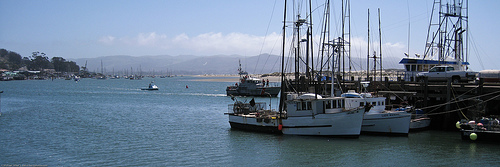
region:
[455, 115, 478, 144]
green things on boat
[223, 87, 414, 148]
2 large white boats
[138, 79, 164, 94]
person in small boat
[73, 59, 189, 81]
boats in the distance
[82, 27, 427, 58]
distant low clouds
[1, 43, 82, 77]
trees in the distance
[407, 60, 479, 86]
white parked truck on dock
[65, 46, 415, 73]
white misty distant mountains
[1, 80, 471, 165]
calm blue pleasant water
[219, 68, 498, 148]
dock with boats nearby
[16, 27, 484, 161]
photo taken near water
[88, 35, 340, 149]
photo taken near water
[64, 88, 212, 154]
water is blue and still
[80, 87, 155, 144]
water is blue and still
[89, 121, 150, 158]
water is blue and still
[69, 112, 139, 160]
water is blue and still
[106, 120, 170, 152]
water is blue and still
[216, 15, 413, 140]
white boats with masts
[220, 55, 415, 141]
two boats next to each other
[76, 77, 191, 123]
small boat going out to sea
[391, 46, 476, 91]
white vehicle on pier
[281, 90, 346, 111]
windows across the front of a boat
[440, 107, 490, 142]
colorful floats on back of boat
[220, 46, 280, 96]
two people in front of a returning boat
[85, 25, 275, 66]
clouds over mountains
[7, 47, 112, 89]
buildings and trees near the water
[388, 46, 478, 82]
flat and low building behind car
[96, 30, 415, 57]
white clouds in the sky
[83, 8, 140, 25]
light blue sky above water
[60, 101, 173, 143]
blue water with little ripples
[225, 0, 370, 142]
A white sale boat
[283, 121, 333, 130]
A black stripe in boat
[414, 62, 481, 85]
A silver pickup truck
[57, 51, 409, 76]
mountains in the background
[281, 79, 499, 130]
A wooden dock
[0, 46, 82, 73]
Trees in the background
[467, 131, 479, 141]
A yellow ball